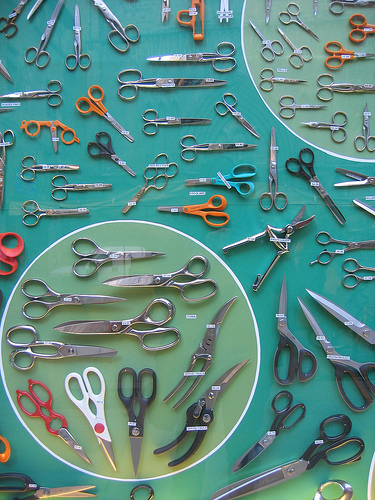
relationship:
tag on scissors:
[212, 172, 236, 197] [54, 397, 139, 499]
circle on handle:
[91, 415, 107, 435] [63, 362, 109, 414]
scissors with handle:
[57, 360, 127, 467] [66, 360, 111, 409]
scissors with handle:
[249, 110, 297, 227] [17, 374, 64, 429]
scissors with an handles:
[156, 195, 234, 225] [186, 213, 230, 231]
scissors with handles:
[118, 59, 240, 164] [206, 165, 259, 224]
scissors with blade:
[156, 292, 244, 412] [204, 299, 242, 341]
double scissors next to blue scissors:
[120, 151, 179, 216] [178, 160, 257, 198]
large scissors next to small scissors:
[212, 408, 365, 498] [228, 385, 306, 472]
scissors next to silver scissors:
[212, 90, 262, 141] [0, 0, 375, 394]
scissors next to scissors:
[49, 172, 112, 204] [19, 152, 80, 185]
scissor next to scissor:
[81, 126, 140, 179] [87, 0, 143, 56]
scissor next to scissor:
[81, 126, 140, 179] [113, 64, 230, 106]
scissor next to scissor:
[81, 126, 140, 179] [282, 143, 350, 230]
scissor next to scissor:
[81, 126, 140, 179] [174, 130, 259, 163]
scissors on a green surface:
[156, 195, 234, 225] [237, 73, 280, 139]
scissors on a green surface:
[179, 132, 258, 160] [237, 73, 280, 139]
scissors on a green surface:
[285, 147, 348, 225] [237, 73, 280, 139]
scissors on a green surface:
[72, 83, 135, 145] [237, 73, 280, 139]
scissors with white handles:
[57, 360, 127, 467] [57, 363, 110, 405]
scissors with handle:
[102, 64, 241, 106] [13, 388, 50, 428]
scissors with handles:
[72, 83, 135, 145] [186, 188, 227, 225]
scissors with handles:
[19, 112, 80, 155] [186, 188, 227, 225]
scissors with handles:
[156, 195, 234, 225] [186, 188, 227, 225]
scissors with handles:
[319, 35, 365, 73] [186, 188, 227, 225]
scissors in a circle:
[0, 232, 257, 477] [17, 205, 260, 494]